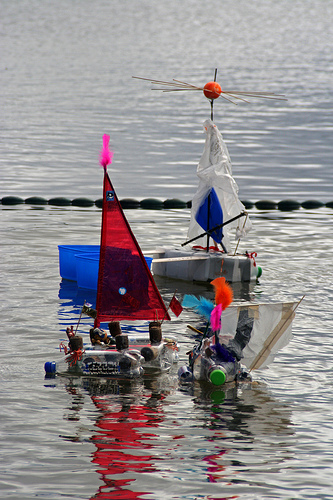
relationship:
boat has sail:
[53, 140, 171, 380] [91, 169, 172, 325]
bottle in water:
[40, 348, 144, 379] [1, 1, 331, 498]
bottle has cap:
[194, 342, 246, 389] [209, 373, 228, 385]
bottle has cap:
[40, 348, 144, 379] [44, 363, 54, 379]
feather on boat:
[104, 136, 110, 169] [53, 140, 171, 380]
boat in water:
[53, 140, 171, 380] [1, 1, 331, 498]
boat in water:
[153, 65, 260, 286] [1, 1, 331, 498]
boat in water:
[190, 280, 303, 389] [1, 1, 331, 498]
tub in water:
[57, 245, 130, 283] [1, 1, 331, 498]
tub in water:
[75, 255, 152, 291] [1, 1, 331, 498]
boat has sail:
[153, 65, 260, 286] [181, 123, 245, 254]